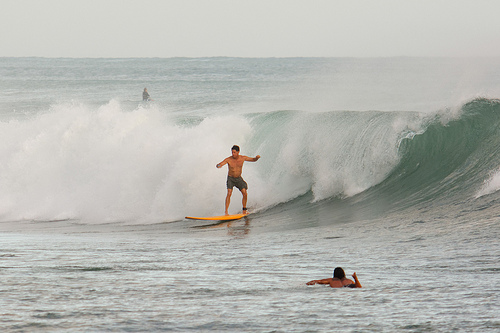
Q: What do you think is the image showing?
A: It is showing an ocean.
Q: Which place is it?
A: It is an ocean.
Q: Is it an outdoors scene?
A: Yes, it is outdoors.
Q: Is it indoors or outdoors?
A: It is outdoors.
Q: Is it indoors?
A: No, it is outdoors.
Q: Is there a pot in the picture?
A: No, there are no pots.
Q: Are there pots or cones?
A: No, there are no pots or cones.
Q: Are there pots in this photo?
A: No, there are no pots.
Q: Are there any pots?
A: No, there are no pots.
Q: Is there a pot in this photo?
A: No, there are no pots.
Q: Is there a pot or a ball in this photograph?
A: No, there are no pots or balls.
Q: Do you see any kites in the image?
A: No, there are no kites.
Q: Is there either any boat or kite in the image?
A: No, there are no kites or boats.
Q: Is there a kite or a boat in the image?
A: No, there are no kites or boats.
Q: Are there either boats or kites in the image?
A: No, there are no kites or boats.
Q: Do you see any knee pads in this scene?
A: No, there are no knee pads.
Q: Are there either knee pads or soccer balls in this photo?
A: No, there are no knee pads or soccer balls.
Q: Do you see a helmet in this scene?
A: No, there are no helmets.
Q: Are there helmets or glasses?
A: No, there are no helmets or glasses.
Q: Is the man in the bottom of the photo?
A: Yes, the man is in the bottom of the image.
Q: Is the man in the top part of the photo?
A: No, the man is in the bottom of the image.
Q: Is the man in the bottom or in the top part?
A: The man is in the bottom of the image.